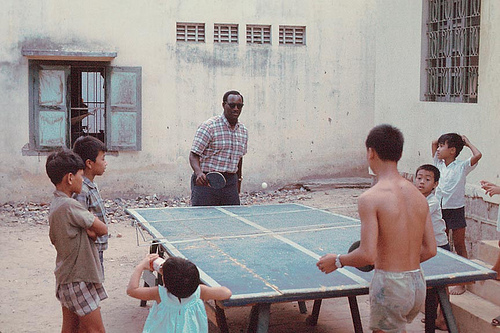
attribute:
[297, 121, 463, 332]
child — standing, small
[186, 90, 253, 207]
man — wearing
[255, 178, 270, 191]
ball — bouncing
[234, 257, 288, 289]
paint — green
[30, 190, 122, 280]
shirt — brown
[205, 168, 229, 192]
paddle — ping pong, game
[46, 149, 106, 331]
child — standing, small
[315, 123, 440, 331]
boy — shirtless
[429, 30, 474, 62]
bars — over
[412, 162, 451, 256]
child — small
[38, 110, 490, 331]
children — little